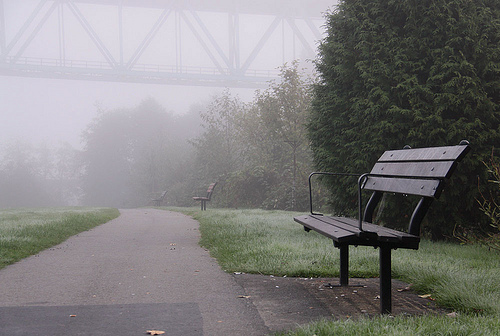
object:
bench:
[290, 139, 473, 313]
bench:
[191, 178, 219, 211]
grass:
[432, 248, 497, 307]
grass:
[0, 213, 46, 251]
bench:
[152, 191, 169, 206]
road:
[3, 205, 254, 332]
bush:
[309, 2, 500, 217]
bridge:
[3, 1, 321, 84]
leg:
[338, 245, 352, 284]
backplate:
[362, 142, 465, 199]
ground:
[2, 206, 500, 336]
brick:
[307, 281, 427, 319]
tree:
[256, 59, 318, 213]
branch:
[272, 107, 299, 152]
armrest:
[307, 172, 363, 217]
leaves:
[264, 77, 280, 85]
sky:
[4, 4, 283, 123]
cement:
[233, 275, 331, 331]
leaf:
[145, 328, 166, 334]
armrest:
[355, 172, 442, 233]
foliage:
[84, 103, 175, 201]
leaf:
[415, 293, 435, 300]